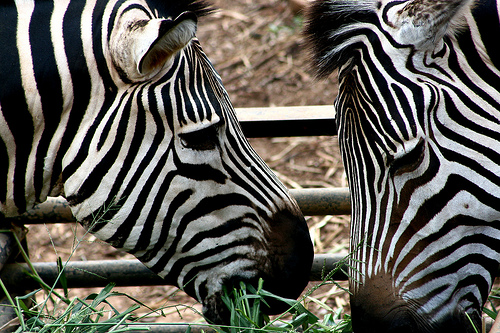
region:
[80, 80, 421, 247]
zebras are seen.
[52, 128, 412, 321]
Two zebras are seen.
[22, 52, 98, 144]
Zebras are black and white color.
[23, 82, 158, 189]
Zebras have stripes in body.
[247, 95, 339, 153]
rail is grey color.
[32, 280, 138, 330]
grass is green color.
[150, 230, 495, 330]
zebras are grassing.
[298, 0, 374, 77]
zebra has short hairs in body.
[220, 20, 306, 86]
ground is brown color.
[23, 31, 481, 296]
day time picture.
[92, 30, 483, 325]
zebra heads close together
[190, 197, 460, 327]
solid black at end of head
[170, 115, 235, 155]
black semicircle of an eye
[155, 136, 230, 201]
two black stripes connecting to form horizontal line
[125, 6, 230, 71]
black edge on hairy ear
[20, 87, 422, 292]
wooden fence behind zebras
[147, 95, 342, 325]
blades of grass at bottom of head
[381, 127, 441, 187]
curved black line below eye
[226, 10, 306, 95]
brown dirt with twigs and grass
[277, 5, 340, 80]
bushy ends of mane hairs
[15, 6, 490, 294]
these are two zebras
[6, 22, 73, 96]
the fur has black and white stripes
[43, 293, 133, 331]
this is the grass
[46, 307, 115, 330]
the grass is green in color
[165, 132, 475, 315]
the zebras are facing each other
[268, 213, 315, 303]
the mouth area is black in color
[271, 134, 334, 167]
this is the ground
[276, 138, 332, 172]
the ground has some dry grass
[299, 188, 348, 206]
this is a grill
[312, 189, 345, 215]
the grill is metallic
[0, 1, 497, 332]
close-up of two zebras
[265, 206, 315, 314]
close-up of zebra nose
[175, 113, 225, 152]
close-up of zebra eye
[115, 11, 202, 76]
close-up of zebra ear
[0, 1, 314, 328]
zebra on left side of pen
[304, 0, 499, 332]
zebra on right side of pen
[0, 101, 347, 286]
three bars of zebra pen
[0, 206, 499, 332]
blades of green grass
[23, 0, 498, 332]
dirt and hay on ground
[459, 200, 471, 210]
dirt smudge on zebra face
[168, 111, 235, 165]
black zebra eye on face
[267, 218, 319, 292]
black nose on zebra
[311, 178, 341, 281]
two metal horizontal poles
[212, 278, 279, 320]
grass in zebra mouth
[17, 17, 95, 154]
stripes on zebra neck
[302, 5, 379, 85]
zebra mane on head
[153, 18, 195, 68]
hair in ear on head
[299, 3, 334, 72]
black tip on mane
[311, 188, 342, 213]
discoloration on metal rod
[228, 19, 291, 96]
dirt on other side of fence